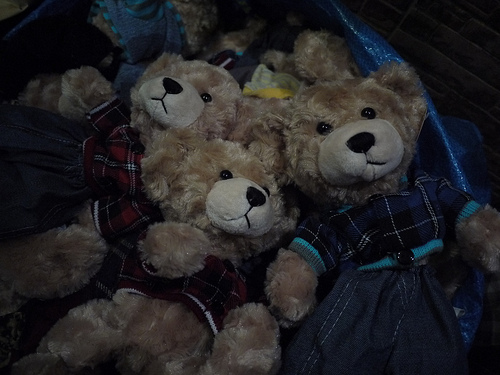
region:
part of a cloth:
[357, 287, 392, 338]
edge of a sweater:
[174, 289, 205, 331]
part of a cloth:
[363, 298, 398, 348]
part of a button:
[193, 283, 235, 333]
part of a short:
[349, 289, 386, 343]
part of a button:
[207, 295, 222, 317]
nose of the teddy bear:
[339, 120, 394, 162]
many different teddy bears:
[68, 92, 454, 317]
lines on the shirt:
[338, 185, 443, 247]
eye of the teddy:
[299, 111, 341, 150]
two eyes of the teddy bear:
[300, 98, 388, 153]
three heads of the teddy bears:
[128, 71, 426, 244]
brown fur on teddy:
[165, 163, 217, 212]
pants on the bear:
[331, 258, 439, 355]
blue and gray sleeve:
[293, 233, 339, 273]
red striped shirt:
[73, 152, 145, 214]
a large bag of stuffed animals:
[14, 6, 481, 373]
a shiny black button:
[391, 240, 413, 269]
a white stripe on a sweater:
[186, 289, 228, 333]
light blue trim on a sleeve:
[462, 200, 482, 217]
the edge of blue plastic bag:
[436, 115, 488, 182]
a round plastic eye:
[304, 107, 338, 137]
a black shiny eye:
[199, 87, 219, 104]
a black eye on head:
[209, 157, 244, 182]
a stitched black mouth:
[360, 156, 389, 173]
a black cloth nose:
[343, 130, 383, 156]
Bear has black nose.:
[160, 70, 200, 118]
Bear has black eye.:
[187, 75, 229, 128]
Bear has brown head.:
[144, 57, 234, 129]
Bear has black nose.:
[238, 180, 275, 215]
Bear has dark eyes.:
[211, 158, 311, 220]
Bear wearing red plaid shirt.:
[157, 240, 243, 337]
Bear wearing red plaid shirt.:
[104, 123, 153, 205]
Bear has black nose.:
[341, 125, 403, 200]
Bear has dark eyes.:
[313, 84, 405, 173]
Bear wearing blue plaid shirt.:
[334, 195, 424, 248]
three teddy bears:
[14, 30, 471, 348]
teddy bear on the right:
[283, 65, 483, 371]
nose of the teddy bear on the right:
[346, 130, 382, 162]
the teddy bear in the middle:
[50, 140, 315, 373]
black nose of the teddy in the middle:
[245, 187, 267, 203]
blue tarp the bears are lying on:
[295, 2, 492, 347]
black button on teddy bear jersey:
[386, 245, 431, 273]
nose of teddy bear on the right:
[151, 73, 191, 104]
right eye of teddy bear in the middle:
[220, 166, 231, 176]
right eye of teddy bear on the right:
[316, 115, 332, 135]